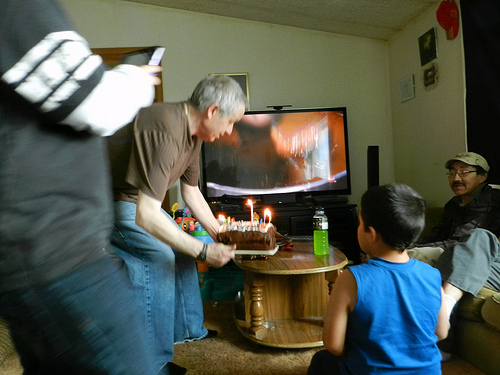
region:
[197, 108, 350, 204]
The flat screen on the black table.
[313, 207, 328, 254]
The plastic bottle on the wooden table.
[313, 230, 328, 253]
The green juice on the table.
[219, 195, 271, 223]
The flames on the candle.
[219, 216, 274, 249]
The chocolate cake on the white platter.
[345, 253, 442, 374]
The blue shirt the child is wearing.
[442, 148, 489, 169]
The hat the man is wearing.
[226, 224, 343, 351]
The wooden table in the center of the room.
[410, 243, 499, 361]
The sofa the man is sitting on.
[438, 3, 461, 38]
The red hat on the wall.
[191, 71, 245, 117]
the man has grey hair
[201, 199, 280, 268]
the man is holding a cake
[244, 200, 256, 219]
a candle is on the cake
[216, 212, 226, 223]
a candle is on the cake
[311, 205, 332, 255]
a bottle is on the table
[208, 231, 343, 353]
the table is made of wood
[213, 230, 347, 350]
the wood is brown in color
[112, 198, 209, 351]
the man is wearing jeans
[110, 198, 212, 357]
the jeans are blue in color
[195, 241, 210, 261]
the man is wearing a watch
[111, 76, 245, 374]
Old man bending over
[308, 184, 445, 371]
Kid is sitting down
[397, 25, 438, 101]
Pictures on the wall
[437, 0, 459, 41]
Red hat on wall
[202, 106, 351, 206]
TV is turned on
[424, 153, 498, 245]
Man with hat and glasses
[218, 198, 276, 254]
A chocolate birthday cake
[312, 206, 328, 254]
Bottle of green liquid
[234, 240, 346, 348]
Table made of wood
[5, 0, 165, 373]
Person holding a phone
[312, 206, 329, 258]
a plastic bottle with green liquid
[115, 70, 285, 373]
a man holding a cake with candles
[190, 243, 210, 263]
a black wristwatch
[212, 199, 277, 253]
a chocolate cake with candles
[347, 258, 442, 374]
a blue sleeveless shirt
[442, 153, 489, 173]
a light colored ball cap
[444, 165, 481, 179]
a pair of glasses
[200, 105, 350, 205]
a flat screen tv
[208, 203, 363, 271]
a short black tv stand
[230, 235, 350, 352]
a rounded wooden table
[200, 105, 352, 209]
a large flat screen tv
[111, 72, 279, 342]
a man leaning forward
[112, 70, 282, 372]
a man holding a chocolate cake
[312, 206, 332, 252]
a plastic bottle with black labeling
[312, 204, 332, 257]
a clear bottle with green liquid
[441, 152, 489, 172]
a light ball cap